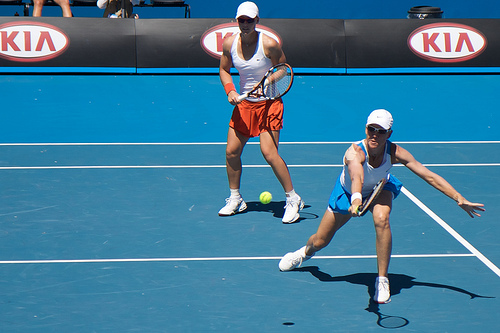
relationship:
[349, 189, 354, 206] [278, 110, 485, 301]
wrist band on man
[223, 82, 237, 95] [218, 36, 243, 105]
band on arm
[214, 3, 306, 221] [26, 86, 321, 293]
man on tennis court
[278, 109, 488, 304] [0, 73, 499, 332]
man on tennis court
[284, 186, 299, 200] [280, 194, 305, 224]
sock on foot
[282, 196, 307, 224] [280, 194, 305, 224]
shoe on foot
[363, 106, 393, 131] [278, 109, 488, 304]
hat on man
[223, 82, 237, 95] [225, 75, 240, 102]
wrist band on arm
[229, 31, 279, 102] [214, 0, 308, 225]
shirt on man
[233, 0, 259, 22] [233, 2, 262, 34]
hat on head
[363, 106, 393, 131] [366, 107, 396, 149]
hat on head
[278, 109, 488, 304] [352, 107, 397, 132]
man wearing hat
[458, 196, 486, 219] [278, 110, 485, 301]
hand of a man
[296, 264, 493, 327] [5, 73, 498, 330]
shadow on court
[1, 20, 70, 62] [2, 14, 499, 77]
kia logo on wall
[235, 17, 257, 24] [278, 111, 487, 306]
sunglasses on woman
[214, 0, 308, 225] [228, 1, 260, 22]
man wearing hat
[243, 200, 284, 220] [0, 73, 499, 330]
shadow on court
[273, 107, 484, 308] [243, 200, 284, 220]
lady casts shadow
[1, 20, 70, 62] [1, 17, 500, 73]
kia logo on barrier